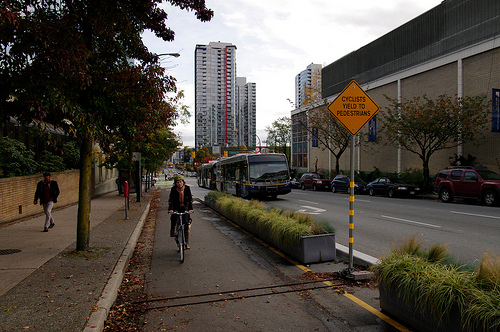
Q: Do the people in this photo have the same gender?
A: No, they are both male and female.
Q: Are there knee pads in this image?
A: No, there are no knee pads.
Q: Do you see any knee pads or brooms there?
A: No, there are no knee pads or brooms.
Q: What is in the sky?
A: The clouds are in the sky.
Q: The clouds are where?
A: The clouds are in the sky.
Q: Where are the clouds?
A: The clouds are in the sky.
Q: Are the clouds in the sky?
A: Yes, the clouds are in the sky.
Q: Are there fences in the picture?
A: No, there are no fences.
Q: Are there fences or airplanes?
A: No, there are no fences or airplanes.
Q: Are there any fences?
A: No, there are no fences.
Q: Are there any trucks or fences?
A: No, there are no fences or trucks.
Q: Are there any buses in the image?
A: Yes, there is a bus.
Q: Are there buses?
A: Yes, there is a bus.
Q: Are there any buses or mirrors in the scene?
A: Yes, there is a bus.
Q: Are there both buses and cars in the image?
A: Yes, there are both a bus and a car.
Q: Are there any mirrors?
A: No, there are no mirrors.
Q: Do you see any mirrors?
A: No, there are no mirrors.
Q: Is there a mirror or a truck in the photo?
A: No, there are no mirrors or trucks.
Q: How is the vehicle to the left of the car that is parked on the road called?
A: The vehicle is a bus.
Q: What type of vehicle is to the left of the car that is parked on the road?
A: The vehicle is a bus.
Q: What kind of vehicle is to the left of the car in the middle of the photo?
A: The vehicle is a bus.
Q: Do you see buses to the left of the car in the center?
A: Yes, there is a bus to the left of the car.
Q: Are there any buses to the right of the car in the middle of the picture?
A: No, the bus is to the left of the car.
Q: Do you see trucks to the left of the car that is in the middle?
A: No, there is a bus to the left of the car.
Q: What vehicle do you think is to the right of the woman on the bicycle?
A: The vehicle is a bus.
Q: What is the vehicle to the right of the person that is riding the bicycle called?
A: The vehicle is a bus.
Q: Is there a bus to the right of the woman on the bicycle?
A: Yes, there is a bus to the right of the woman.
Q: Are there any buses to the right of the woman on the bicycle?
A: Yes, there is a bus to the right of the woman.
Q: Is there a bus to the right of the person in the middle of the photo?
A: Yes, there is a bus to the right of the woman.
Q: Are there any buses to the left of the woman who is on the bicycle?
A: No, the bus is to the right of the woman.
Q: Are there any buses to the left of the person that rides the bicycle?
A: No, the bus is to the right of the woman.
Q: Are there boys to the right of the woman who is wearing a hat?
A: No, there is a bus to the right of the woman.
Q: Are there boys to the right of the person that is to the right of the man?
A: No, there is a bus to the right of the woman.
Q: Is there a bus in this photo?
A: Yes, there is a bus.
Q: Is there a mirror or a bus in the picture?
A: Yes, there is a bus.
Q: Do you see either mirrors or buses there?
A: Yes, there is a bus.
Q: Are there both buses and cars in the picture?
A: Yes, there are both a bus and a car.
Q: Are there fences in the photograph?
A: No, there are no fences.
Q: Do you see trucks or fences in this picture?
A: No, there are no fences or trucks.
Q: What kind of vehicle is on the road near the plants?
A: The vehicle is a bus.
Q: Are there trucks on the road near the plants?
A: No, there is a bus on the road.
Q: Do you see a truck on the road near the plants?
A: No, there is a bus on the road.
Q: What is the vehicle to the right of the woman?
A: The vehicle is a bus.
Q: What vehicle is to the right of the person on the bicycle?
A: The vehicle is a bus.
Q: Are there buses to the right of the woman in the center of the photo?
A: Yes, there is a bus to the right of the woman.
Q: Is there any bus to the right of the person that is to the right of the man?
A: Yes, there is a bus to the right of the woman.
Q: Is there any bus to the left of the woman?
A: No, the bus is to the right of the woman.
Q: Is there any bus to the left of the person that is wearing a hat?
A: No, the bus is to the right of the woman.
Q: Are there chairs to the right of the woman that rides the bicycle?
A: No, there is a bus to the right of the woman.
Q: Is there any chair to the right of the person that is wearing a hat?
A: No, there is a bus to the right of the woman.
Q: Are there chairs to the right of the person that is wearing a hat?
A: No, there is a bus to the right of the woman.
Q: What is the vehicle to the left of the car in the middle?
A: The vehicle is a bus.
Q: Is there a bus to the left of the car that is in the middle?
A: Yes, there is a bus to the left of the car.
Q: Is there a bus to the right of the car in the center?
A: No, the bus is to the left of the car.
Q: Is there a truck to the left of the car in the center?
A: No, there is a bus to the left of the car.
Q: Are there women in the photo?
A: Yes, there is a woman.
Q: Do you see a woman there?
A: Yes, there is a woman.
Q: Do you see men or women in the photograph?
A: Yes, there is a woman.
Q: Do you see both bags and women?
A: No, there is a woman but no bags.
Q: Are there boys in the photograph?
A: No, there are no boys.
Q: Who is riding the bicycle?
A: The woman is riding the bicycle.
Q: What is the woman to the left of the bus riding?
A: The woman is riding the bicycle.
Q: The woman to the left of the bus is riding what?
A: The woman is riding the bicycle.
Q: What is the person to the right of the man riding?
A: The woman is riding the bicycle.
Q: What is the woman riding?
A: The woman is riding the bicycle.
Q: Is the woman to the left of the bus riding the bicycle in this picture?
A: Yes, the woman is riding the bicycle.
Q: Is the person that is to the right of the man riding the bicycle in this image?
A: Yes, the woman is riding the bicycle.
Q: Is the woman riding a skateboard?
A: No, the woman is riding the bicycle.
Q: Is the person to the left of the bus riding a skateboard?
A: No, the woman is riding the bicycle.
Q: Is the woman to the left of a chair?
A: No, the woman is to the left of the bus.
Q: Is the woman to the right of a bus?
A: No, the woman is to the left of a bus.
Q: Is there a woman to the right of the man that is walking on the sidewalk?
A: Yes, there is a woman to the right of the man.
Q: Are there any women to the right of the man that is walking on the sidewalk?
A: Yes, there is a woman to the right of the man.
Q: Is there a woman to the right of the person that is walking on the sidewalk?
A: Yes, there is a woman to the right of the man.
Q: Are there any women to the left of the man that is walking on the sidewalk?
A: No, the woman is to the right of the man.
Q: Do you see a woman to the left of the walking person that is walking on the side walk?
A: No, the woman is to the right of the man.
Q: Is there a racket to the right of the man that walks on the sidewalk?
A: No, there is a woman to the right of the man.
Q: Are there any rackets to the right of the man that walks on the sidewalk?
A: No, there is a woman to the right of the man.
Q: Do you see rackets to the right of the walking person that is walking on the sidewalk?
A: No, there is a woman to the right of the man.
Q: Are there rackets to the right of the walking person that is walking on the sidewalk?
A: No, there is a woman to the right of the man.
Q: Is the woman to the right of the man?
A: Yes, the woman is to the right of the man.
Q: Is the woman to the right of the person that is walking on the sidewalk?
A: Yes, the woman is to the right of the man.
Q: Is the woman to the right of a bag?
A: No, the woman is to the right of the man.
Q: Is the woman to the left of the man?
A: No, the woman is to the right of the man.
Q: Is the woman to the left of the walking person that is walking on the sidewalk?
A: No, the woman is to the right of the man.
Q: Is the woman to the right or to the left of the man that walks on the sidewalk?
A: The woman is to the right of the man.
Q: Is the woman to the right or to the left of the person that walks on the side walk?
A: The woman is to the right of the man.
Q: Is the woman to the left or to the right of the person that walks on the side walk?
A: The woman is to the right of the man.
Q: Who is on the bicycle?
A: The woman is on the bicycle.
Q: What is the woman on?
A: The woman is on the bicycle.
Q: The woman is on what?
A: The woman is on the bicycle.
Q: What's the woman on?
A: The woman is on the bicycle.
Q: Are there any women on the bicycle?
A: Yes, there is a woman on the bicycle.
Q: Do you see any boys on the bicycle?
A: No, there is a woman on the bicycle.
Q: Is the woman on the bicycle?
A: Yes, the woman is on the bicycle.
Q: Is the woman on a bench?
A: No, the woman is on the bicycle.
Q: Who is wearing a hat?
A: The woman is wearing a hat.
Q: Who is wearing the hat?
A: The woman is wearing a hat.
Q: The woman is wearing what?
A: The woman is wearing a hat.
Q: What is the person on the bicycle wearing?
A: The woman is wearing a hat.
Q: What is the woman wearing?
A: The woman is wearing a hat.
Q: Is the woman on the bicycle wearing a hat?
A: Yes, the woman is wearing a hat.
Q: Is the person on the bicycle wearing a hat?
A: Yes, the woman is wearing a hat.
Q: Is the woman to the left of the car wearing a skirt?
A: No, the woman is wearing a hat.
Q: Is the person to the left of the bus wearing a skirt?
A: No, the woman is wearing a hat.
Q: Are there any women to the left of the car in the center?
A: Yes, there is a woman to the left of the car.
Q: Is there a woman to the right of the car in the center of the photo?
A: No, the woman is to the left of the car.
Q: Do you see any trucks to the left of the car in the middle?
A: No, there is a woman to the left of the car.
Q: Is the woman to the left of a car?
A: Yes, the woman is to the left of a car.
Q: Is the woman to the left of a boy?
A: No, the woman is to the left of a car.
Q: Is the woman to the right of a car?
A: No, the woman is to the left of a car.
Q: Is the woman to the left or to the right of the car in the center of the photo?
A: The woman is to the left of the car.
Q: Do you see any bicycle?
A: Yes, there is a bicycle.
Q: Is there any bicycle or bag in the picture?
A: Yes, there is a bicycle.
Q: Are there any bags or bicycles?
A: Yes, there is a bicycle.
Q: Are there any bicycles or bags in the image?
A: Yes, there is a bicycle.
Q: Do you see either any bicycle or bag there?
A: Yes, there is a bicycle.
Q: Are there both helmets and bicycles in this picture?
A: No, there is a bicycle but no helmets.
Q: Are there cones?
A: No, there are no cones.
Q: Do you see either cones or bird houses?
A: No, there are no cones or bird houses.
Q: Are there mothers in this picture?
A: No, there are no mothers.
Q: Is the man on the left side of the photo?
A: Yes, the man is on the left of the image.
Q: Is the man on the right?
A: No, the man is on the left of the image.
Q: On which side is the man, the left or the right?
A: The man is on the left of the image.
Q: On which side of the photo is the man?
A: The man is on the left of the image.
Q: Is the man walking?
A: Yes, the man is walking.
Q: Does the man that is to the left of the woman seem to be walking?
A: Yes, the man is walking.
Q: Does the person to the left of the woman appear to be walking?
A: Yes, the man is walking.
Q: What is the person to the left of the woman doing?
A: The man is walking.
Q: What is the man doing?
A: The man is walking.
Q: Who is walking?
A: The man is walking.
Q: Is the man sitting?
A: No, the man is walking.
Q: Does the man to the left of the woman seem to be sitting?
A: No, the man is walking.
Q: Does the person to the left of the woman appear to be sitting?
A: No, the man is walking.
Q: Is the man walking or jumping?
A: The man is walking.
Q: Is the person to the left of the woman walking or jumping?
A: The man is walking.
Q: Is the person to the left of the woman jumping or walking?
A: The man is walking.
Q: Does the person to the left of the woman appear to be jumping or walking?
A: The man is walking.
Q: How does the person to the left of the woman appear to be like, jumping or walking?
A: The man is walking.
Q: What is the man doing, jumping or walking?
A: The man is walking.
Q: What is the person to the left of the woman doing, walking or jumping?
A: The man is walking.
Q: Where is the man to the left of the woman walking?
A: The man is walking on the side walk.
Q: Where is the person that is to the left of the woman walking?
A: The man is walking on the side walk.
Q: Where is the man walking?
A: The man is walking on the side walk.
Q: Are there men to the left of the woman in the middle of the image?
A: Yes, there is a man to the left of the woman.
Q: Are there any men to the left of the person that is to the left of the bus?
A: Yes, there is a man to the left of the woman.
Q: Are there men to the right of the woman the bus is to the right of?
A: No, the man is to the left of the woman.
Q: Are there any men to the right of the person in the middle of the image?
A: No, the man is to the left of the woman.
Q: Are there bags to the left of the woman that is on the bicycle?
A: No, there is a man to the left of the woman.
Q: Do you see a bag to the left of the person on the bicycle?
A: No, there is a man to the left of the woman.